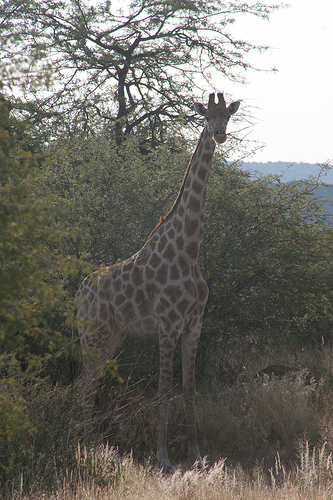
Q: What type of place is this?
A: It is a yard.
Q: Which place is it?
A: It is a yard.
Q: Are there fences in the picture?
A: No, there are no fences.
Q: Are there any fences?
A: No, there are no fences.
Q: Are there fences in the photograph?
A: No, there are no fences.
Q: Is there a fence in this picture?
A: No, there are no fences.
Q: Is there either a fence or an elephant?
A: No, there are no fences or elephants.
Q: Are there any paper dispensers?
A: No, there are no paper dispensers.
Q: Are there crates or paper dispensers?
A: No, there are no paper dispensers or crates.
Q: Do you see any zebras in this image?
A: No, there are no zebras.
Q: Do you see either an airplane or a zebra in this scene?
A: No, there are no zebras or airplanes.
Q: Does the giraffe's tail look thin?
A: Yes, the tail is thin.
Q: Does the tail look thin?
A: Yes, the tail is thin.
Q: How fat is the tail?
A: The tail is thin.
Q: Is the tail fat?
A: No, the tail is thin.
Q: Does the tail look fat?
A: No, the tail is thin.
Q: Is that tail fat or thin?
A: The tail is thin.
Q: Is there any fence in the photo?
A: No, there are no fences.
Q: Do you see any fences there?
A: No, there are no fences.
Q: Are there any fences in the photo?
A: No, there are no fences.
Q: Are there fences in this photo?
A: No, there are no fences.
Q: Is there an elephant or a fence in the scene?
A: No, there are no fences or elephants.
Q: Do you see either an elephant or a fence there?
A: No, there are no fences or elephants.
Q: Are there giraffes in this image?
A: Yes, there is a giraffe.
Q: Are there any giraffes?
A: Yes, there is a giraffe.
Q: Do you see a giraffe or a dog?
A: Yes, there is a giraffe.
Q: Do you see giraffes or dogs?
A: Yes, there is a giraffe.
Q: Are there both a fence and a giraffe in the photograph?
A: No, there is a giraffe but no fences.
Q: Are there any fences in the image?
A: No, there are no fences.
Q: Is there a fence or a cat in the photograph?
A: No, there are no fences or cats.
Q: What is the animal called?
A: The animal is a giraffe.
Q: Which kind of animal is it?
A: The animal is a giraffe.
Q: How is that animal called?
A: That is a giraffe.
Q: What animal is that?
A: That is a giraffe.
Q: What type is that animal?
A: That is a giraffe.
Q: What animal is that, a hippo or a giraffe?
A: That is a giraffe.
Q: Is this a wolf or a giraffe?
A: This is a giraffe.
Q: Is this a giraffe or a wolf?
A: This is a giraffe.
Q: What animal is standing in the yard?
A: The animal is a giraffe.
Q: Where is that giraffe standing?
A: The giraffe is standing in the yard.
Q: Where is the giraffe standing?
A: The giraffe is standing in the yard.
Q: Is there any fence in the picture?
A: No, there are no fences.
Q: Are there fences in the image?
A: No, there are no fences.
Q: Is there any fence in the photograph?
A: No, there are no fences.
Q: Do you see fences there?
A: No, there are no fences.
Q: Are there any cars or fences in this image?
A: No, there are no fences or cars.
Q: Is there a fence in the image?
A: No, there are no fences.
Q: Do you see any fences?
A: No, there are no fences.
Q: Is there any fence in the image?
A: No, there are no fences.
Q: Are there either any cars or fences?
A: No, there are no fences or cars.